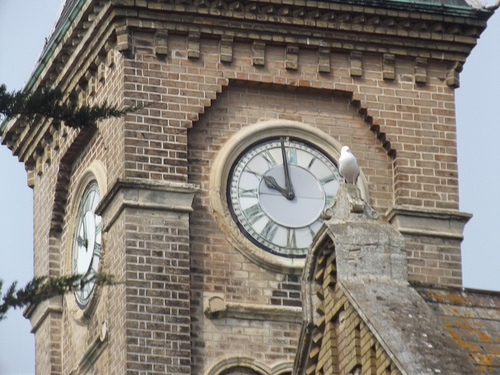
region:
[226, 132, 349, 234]
its almost ten o`clock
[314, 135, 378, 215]
a white bird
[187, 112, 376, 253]
a white faced clock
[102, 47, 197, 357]
building made of bricks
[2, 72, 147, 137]
a green tree branch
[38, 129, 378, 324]
two clocks on the building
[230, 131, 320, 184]
roman numerals for numbers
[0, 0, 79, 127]
green border on the top of building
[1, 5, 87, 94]
overcast cloudy day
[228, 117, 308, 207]
the hands on the clock are black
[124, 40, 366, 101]
this is a building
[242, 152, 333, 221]
this is a clock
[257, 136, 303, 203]
the time is ten oclock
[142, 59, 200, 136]
the wall is made of bricks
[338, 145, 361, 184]
this is a dove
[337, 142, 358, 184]
the dove is white in color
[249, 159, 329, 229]
the clock is white in color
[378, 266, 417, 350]
the roof is old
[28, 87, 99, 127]
the branch is long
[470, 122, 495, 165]
the sky is blue in color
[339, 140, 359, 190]
this is a bird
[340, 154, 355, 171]
the bird is white in color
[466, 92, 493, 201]
this is the sky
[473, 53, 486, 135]
the sky is blue in color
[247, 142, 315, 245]
this is a watch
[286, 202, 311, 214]
the watch is white in color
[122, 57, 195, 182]
this is the wall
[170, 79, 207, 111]
the wall is made of bricks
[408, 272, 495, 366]
this is the roof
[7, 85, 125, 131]
this is a tree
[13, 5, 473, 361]
brick tower with clocks set inward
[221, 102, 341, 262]
clock showing it is almost 10:00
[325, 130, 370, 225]
white bird sitting on top of roof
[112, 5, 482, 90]
bricks and stone decorating top of tower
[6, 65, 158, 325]
a couple of branches extending toward building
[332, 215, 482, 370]
dark and white markings on the roof edging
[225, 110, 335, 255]
roman numerals set in white circle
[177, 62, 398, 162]
jagged and smooth brickwork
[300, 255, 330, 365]
corners of bricks sticking out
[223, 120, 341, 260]
circle of grey lines marking each minute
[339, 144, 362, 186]
white and grey seagull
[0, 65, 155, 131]
branch of tree in foreground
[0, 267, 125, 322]
small branch of tree in foreground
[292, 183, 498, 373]
tip of old church roof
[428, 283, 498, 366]
rust-colored moss growing on roof shingles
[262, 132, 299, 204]
black wrought iron clock hands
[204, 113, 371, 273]
large clock face on tower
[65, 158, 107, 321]
clock face at slight angle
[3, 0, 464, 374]
large brick clock tower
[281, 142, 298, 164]
iodized numeral XII on clock of tower